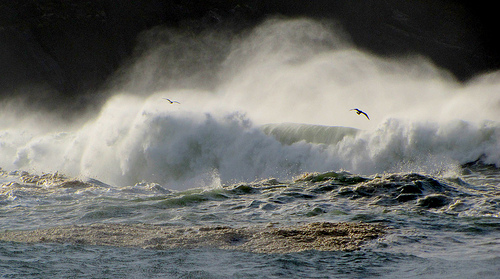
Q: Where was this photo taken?
A: The sea.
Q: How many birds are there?
A: 2.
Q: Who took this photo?
A: A tourist.